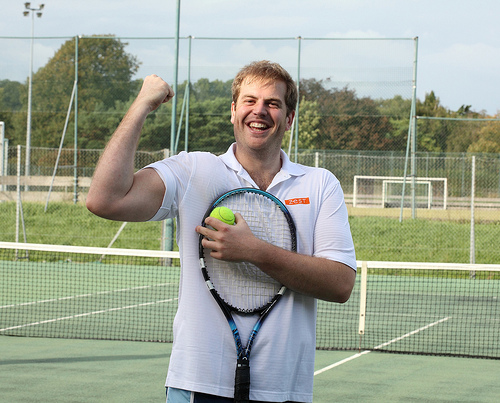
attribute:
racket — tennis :
[185, 171, 310, 401]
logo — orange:
[286, 195, 312, 210]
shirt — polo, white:
[148, 146, 359, 401]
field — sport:
[83, 96, 475, 371]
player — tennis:
[84, 58, 357, 400]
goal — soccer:
[351, 172, 449, 210]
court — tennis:
[0, 260, 497, 402]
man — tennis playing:
[104, 50, 425, 394]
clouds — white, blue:
[137, 42, 208, 71]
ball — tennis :
[204, 201, 239, 231]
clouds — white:
[323, 21, 387, 62]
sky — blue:
[4, 2, 496, 86]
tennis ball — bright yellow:
[207, 201, 239, 227]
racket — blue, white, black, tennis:
[196, 178, 301, 401]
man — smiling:
[84, 35, 389, 398]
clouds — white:
[24, 42, 54, 67]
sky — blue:
[10, 7, 469, 89]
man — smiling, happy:
[83, 57, 359, 402]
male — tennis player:
[82, 48, 364, 402]